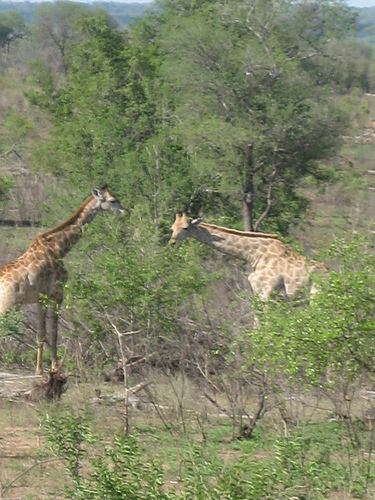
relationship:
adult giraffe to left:
[8, 172, 146, 422] [13, 9, 160, 420]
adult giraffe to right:
[157, 189, 369, 410] [172, 9, 369, 405]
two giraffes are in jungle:
[5, 177, 352, 405] [0, 1, 369, 495]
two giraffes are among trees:
[5, 177, 352, 405] [0, 7, 367, 315]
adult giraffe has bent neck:
[157, 189, 369, 410] [200, 213, 271, 263]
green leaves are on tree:
[81, 26, 175, 97] [32, 15, 224, 316]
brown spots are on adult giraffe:
[22, 239, 57, 265] [8, 172, 146, 422]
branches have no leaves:
[87, 300, 161, 416] [123, 325, 177, 381]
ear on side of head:
[90, 186, 109, 199] [81, 184, 130, 223]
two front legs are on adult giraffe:
[30, 278, 77, 382] [8, 172, 146, 422]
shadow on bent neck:
[192, 230, 237, 253] [200, 213, 271, 263]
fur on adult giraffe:
[28, 195, 89, 251] [8, 172, 146, 422]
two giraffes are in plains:
[5, 177, 352, 405] [25, 50, 347, 466]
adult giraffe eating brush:
[157, 189, 369, 410] [75, 240, 208, 326]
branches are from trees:
[87, 300, 161, 416] [0, 7, 367, 315]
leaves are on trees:
[236, 259, 369, 399] [0, 7, 367, 315]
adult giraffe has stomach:
[8, 172, 146, 422] [11, 263, 61, 314]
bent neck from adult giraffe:
[200, 213, 271, 263] [157, 189, 369, 410]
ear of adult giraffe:
[90, 186, 109, 199] [8, 172, 146, 422]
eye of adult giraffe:
[108, 193, 125, 205] [8, 172, 146, 422]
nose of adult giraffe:
[121, 207, 146, 219] [8, 172, 146, 422]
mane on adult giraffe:
[200, 213, 271, 263] [167, 208, 369, 410]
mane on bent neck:
[200, 213, 271, 263] [195, 218, 254, 268]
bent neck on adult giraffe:
[195, 218, 254, 268] [167, 208, 369, 410]